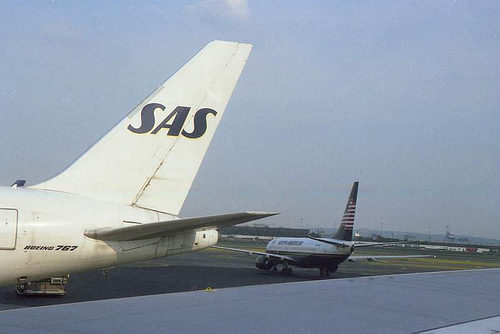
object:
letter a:
[151, 106, 191, 136]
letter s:
[127, 103, 165, 134]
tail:
[26, 39, 249, 216]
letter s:
[181, 107, 217, 137]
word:
[24, 246, 54, 251]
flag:
[341, 199, 356, 230]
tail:
[332, 181, 358, 239]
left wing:
[211, 246, 295, 261]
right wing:
[349, 255, 434, 258]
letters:
[281, 241, 287, 245]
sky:
[0, 1, 497, 232]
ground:
[1, 239, 498, 332]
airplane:
[0, 40, 281, 295]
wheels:
[281, 268, 292, 276]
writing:
[127, 103, 216, 138]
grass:
[384, 258, 499, 268]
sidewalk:
[0, 268, 499, 333]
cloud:
[221, 0, 246, 16]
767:
[56, 245, 78, 251]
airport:
[0, 0, 496, 333]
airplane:
[210, 181, 434, 279]